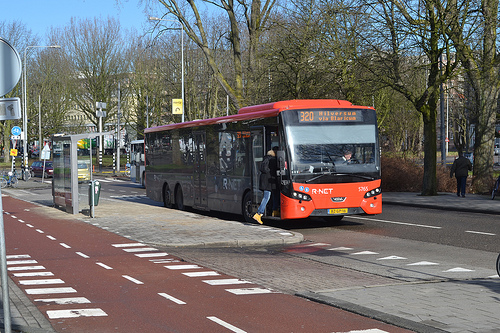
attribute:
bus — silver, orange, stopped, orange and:
[145, 100, 383, 225]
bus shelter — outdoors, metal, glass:
[51, 132, 114, 219]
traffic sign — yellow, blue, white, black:
[171, 98, 183, 114]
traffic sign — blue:
[10, 125, 22, 135]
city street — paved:
[0, 166, 499, 332]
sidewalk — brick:
[0, 274, 54, 333]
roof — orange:
[143, 100, 376, 134]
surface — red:
[0, 195, 419, 332]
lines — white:
[1, 209, 388, 332]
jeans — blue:
[257, 190, 272, 215]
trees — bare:
[0, 1, 499, 197]